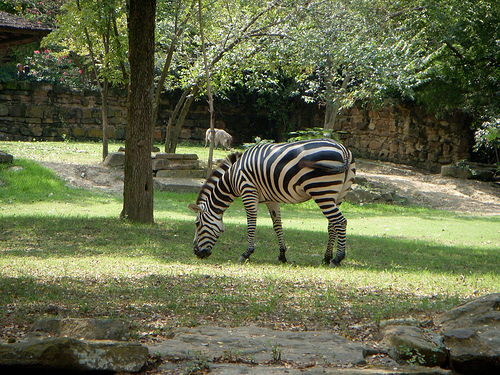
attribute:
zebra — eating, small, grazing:
[190, 148, 356, 268]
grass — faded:
[6, 258, 377, 345]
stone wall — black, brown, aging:
[3, 30, 102, 140]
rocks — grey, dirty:
[174, 326, 362, 374]